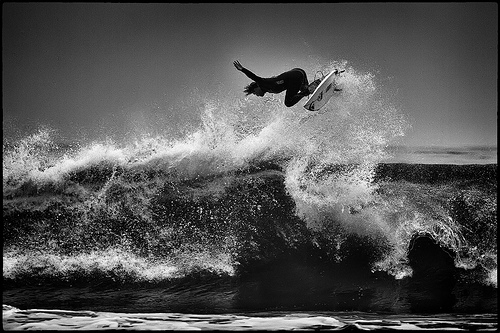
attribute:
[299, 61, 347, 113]
surfboard — black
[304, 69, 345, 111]
surfboard — white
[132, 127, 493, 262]
wave — white, ocean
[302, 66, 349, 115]
surfboard — white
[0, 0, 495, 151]
sky — dark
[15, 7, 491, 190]
sky — clear, calm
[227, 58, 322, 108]
man — surfing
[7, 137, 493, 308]
wave — water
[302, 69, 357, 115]
surfboard — white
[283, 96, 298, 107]
knee — bent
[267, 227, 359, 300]
water — dark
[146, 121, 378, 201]
foam — white, sea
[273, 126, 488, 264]
wave — high